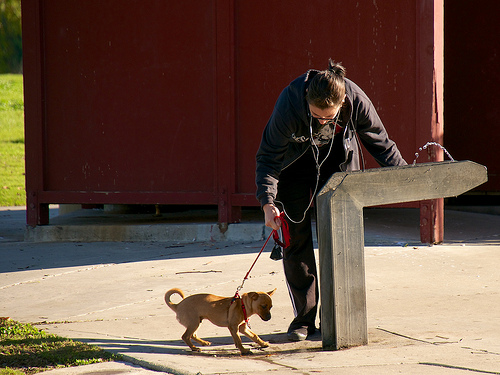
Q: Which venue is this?
A: This is a pavement.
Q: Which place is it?
A: It is a pavement.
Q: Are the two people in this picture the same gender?
A: Yes, all the people are female.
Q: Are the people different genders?
A: No, all the people are female.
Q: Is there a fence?
A: No, there are no fences.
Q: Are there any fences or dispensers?
A: No, there are no fences or dispensers.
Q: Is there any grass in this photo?
A: Yes, there is grass.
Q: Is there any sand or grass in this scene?
A: Yes, there is grass.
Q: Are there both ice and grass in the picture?
A: No, there is grass but no ice.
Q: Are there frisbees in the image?
A: No, there are no frisbees.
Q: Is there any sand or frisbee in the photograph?
A: No, there are no frisbees or sand.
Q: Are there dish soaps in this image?
A: No, there are no dish soaps.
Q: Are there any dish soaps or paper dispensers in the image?
A: No, there are no dish soaps or paper dispensers.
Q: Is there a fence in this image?
A: No, there are no fences.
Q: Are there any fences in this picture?
A: No, there are no fences.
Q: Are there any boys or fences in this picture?
A: No, there are no fences or boys.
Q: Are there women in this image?
A: Yes, there is a woman.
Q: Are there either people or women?
A: Yes, there is a woman.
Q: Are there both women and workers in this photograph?
A: No, there is a woman but no workers.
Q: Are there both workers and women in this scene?
A: No, there is a woman but no workers.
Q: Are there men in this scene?
A: No, there are no men.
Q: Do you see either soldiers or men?
A: No, there are no men or soldiers.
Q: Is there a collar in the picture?
A: Yes, there is a collar.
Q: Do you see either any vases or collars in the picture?
A: Yes, there is a collar.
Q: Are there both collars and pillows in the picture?
A: No, there is a collar but no pillows.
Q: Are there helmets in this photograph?
A: No, there are no helmets.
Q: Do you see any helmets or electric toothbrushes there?
A: No, there are no helmets or electric toothbrushes.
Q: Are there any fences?
A: No, there are no fences.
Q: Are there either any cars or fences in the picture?
A: No, there are no fences or cars.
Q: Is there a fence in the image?
A: No, there are no fences.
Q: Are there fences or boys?
A: No, there are no fences or boys.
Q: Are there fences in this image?
A: No, there are no fences.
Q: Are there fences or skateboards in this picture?
A: No, there are no fences or skateboards.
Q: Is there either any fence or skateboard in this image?
A: No, there are no fences or skateboards.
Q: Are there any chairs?
A: No, there are no chairs.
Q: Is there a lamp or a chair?
A: No, there are no chairs or lamps.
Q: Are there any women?
A: Yes, there is a woman.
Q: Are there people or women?
A: Yes, there is a woman.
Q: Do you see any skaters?
A: No, there are no skaters.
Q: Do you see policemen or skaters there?
A: No, there are no skaters or policemen.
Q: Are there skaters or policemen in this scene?
A: No, there are no skaters or policemen.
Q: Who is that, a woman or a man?
A: That is a woman.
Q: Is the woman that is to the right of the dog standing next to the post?
A: Yes, the woman is standing next to the post.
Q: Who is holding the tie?
A: The woman is holding the tie.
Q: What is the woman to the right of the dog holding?
A: The woman is holding the necktie.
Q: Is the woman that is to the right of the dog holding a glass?
A: No, the woman is holding the tie.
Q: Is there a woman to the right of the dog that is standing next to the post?
A: Yes, there is a woman to the right of the dog.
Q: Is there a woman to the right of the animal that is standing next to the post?
A: Yes, there is a woman to the right of the dog.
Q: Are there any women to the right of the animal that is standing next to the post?
A: Yes, there is a woman to the right of the dog.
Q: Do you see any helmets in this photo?
A: No, there are no helmets.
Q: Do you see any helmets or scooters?
A: No, there are no helmets or scooters.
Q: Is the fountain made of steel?
A: Yes, the fountain is made of steel.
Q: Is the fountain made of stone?
A: No, the fountain is made of steel.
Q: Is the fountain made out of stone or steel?
A: The fountain is made of steel.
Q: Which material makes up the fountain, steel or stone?
A: The fountain is made of steel.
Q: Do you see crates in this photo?
A: No, there are no crates.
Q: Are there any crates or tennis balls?
A: No, there are no crates or tennis balls.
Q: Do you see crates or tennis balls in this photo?
A: No, there are no crates or tennis balls.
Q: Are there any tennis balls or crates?
A: No, there are no crates or tennis balls.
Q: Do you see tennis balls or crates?
A: No, there are no crates or tennis balls.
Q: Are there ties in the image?
A: Yes, there is a tie.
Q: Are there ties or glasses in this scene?
A: Yes, there is a tie.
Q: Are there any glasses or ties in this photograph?
A: Yes, there is a tie.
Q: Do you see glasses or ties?
A: Yes, there is a tie.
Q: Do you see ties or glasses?
A: Yes, there is a tie.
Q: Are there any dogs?
A: Yes, there is a dog.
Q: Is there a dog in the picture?
A: Yes, there is a dog.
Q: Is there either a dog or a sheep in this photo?
A: Yes, there is a dog.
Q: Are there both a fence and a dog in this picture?
A: No, there is a dog but no fences.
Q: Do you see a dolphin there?
A: No, there are no dolphins.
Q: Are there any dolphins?
A: No, there are no dolphins.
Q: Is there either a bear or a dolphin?
A: No, there are no dolphins or bears.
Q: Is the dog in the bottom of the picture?
A: Yes, the dog is in the bottom of the image.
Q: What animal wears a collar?
A: The dog wears a collar.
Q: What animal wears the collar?
A: The dog wears a collar.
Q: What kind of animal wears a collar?
A: The animal is a dog.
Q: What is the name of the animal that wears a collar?
A: The animal is a dog.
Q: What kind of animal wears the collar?
A: The animal is a dog.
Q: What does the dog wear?
A: The dog wears a collar.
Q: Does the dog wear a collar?
A: Yes, the dog wears a collar.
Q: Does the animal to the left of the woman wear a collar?
A: Yes, the dog wears a collar.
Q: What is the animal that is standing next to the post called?
A: The animal is a dog.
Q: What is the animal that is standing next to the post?
A: The animal is a dog.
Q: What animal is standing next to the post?
A: The animal is a dog.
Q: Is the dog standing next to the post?
A: Yes, the dog is standing next to the post.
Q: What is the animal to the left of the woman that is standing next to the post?
A: The animal is a dog.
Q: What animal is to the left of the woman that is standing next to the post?
A: The animal is a dog.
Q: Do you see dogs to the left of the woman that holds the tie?
A: Yes, there is a dog to the left of the woman.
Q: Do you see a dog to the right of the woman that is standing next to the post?
A: No, the dog is to the left of the woman.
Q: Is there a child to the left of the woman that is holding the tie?
A: No, there is a dog to the left of the woman.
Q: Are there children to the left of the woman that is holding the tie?
A: No, there is a dog to the left of the woman.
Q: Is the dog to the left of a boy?
A: No, the dog is to the left of a woman.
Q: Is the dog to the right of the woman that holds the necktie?
A: No, the dog is to the left of the woman.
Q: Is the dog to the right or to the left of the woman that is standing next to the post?
A: The dog is to the left of the woman.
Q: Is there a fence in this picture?
A: No, there are no fences.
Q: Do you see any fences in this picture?
A: No, there are no fences.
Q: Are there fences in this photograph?
A: No, there are no fences.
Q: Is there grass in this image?
A: Yes, there is grass.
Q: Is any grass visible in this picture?
A: Yes, there is grass.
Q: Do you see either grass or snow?
A: Yes, there is grass.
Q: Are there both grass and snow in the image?
A: No, there is grass but no snow.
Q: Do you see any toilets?
A: No, there are no toilets.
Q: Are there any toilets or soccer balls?
A: No, there are no toilets or soccer balls.